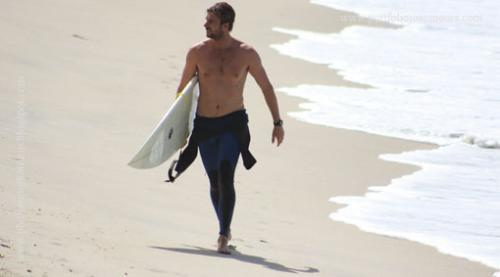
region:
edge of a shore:
[341, 82, 407, 127]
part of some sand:
[259, 202, 299, 255]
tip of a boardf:
[126, 150, 154, 192]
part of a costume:
[216, 179, 247, 224]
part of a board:
[156, 120, 178, 150]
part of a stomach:
[211, 87, 237, 104]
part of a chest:
[216, 47, 242, 82]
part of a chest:
[214, 51, 256, 88]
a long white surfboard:
[125, 71, 205, 170]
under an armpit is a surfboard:
[136, 42, 203, 171]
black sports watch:
[272, 114, 282, 124]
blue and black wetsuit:
[166, 106, 258, 233]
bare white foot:
[215, 233, 232, 253]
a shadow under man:
[145, 237, 323, 272]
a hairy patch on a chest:
[214, 51, 226, 77]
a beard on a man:
[204, 23, 224, 39]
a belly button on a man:
[213, 102, 220, 110]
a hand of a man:
[271, 125, 285, 143]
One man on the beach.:
[145, 0, 282, 265]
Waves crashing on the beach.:
[292, 5, 490, 265]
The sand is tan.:
[9, 2, 343, 268]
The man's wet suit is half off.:
[162, 15, 272, 267]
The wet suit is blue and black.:
[170, 98, 271, 255]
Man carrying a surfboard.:
[130, 2, 298, 269]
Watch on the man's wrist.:
[272, 112, 300, 129]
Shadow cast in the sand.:
[157, 233, 327, 273]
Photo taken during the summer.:
[4, 22, 493, 265]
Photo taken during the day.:
[10, 5, 491, 267]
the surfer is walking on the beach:
[131, 0, 326, 269]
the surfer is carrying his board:
[131, 5, 316, 270]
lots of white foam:
[307, 30, 419, 175]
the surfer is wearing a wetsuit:
[185, 100, 255, 240]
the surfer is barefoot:
[205, 225, 246, 258]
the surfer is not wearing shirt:
[180, 40, 276, 128]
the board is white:
[140, 110, 195, 175]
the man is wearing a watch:
[265, 115, 300, 131]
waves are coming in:
[276, 12, 496, 265]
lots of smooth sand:
[22, 27, 106, 249]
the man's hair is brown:
[199, 1, 241, 53]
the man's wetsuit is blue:
[200, 127, 261, 254]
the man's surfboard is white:
[118, 74, 223, 194]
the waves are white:
[293, 10, 495, 244]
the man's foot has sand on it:
[203, 222, 266, 267]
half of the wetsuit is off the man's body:
[172, 40, 278, 111]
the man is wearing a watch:
[258, 106, 324, 148]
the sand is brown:
[3, 10, 433, 273]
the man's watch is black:
[255, 107, 327, 146]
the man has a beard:
[199, 25, 236, 50]